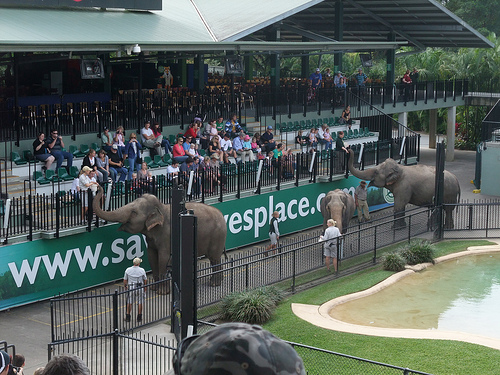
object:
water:
[328, 250, 500, 346]